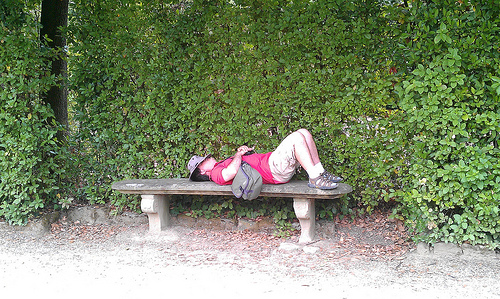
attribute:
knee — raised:
[296, 125, 314, 147]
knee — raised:
[279, 132, 309, 154]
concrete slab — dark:
[110, 176, 352, 198]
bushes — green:
[152, 13, 401, 210]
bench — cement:
[101, 156, 369, 253]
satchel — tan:
[228, 162, 261, 201]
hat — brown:
[180, 151, 214, 180]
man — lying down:
[188, 130, 356, 188]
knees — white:
[288, 115, 316, 145]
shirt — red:
[211, 151, 278, 185]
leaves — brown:
[207, 229, 267, 264]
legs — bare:
[284, 124, 323, 174]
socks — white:
[296, 155, 336, 181]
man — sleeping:
[179, 126, 339, 196]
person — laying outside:
[168, 125, 349, 207]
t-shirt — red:
[206, 152, 275, 188]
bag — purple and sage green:
[232, 161, 263, 201]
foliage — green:
[124, 39, 196, 97]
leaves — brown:
[42, 201, 409, 266]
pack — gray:
[228, 157, 265, 202]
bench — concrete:
[106, 177, 355, 244]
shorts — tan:
[269, 133, 301, 182]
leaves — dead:
[179, 217, 288, 252]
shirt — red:
[205, 149, 278, 184]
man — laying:
[182, 121, 344, 195]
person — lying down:
[175, 121, 346, 195]